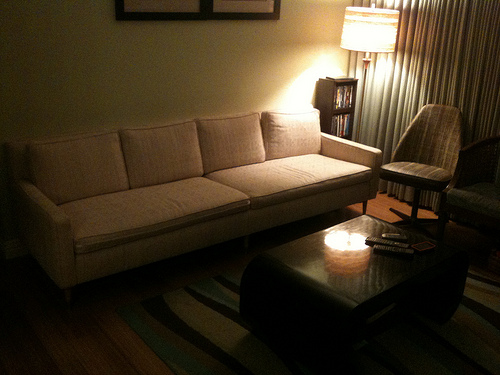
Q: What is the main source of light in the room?
A: The lamp.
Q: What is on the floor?
A: A rug.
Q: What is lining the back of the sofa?
A: Cushions.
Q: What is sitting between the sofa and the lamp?
A: A small bookcase.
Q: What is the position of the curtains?
A: Closed.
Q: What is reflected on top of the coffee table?
A: The lamp.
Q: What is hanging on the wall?
A: Framed art.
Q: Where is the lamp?
A: In the corner of the room.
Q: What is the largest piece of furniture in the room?
A: The couch.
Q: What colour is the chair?
A: Gray.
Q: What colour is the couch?
A: White.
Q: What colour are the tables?
A: Brown.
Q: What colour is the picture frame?
A: Brown.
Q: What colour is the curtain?
A: Gray.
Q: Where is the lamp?
A: In the corner.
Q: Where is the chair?
A: Beside the sofa.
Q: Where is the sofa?
A: Against the wall.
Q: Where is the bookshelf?
A: Behind the lamp.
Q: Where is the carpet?
A: On the floor.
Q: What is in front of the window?
A: Curtains.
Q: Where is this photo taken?
A: LIving room.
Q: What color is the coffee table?
A: Black.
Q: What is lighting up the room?
A: Lamp.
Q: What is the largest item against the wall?
A: Couch.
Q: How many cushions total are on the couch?
A: Six.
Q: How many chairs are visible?
A: Two.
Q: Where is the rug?
A: Under coffee table.